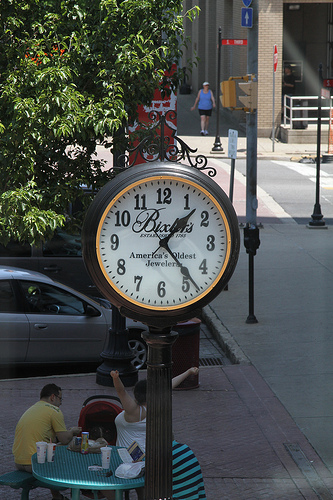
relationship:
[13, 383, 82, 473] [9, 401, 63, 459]
man wearing shirt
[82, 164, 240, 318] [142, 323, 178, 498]
clock on pole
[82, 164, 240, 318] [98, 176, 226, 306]
clock has face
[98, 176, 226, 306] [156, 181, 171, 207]
face has number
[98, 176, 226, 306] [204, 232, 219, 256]
face has number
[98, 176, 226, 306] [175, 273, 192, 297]
face has number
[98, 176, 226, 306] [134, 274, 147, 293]
face has number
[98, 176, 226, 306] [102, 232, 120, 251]
face has number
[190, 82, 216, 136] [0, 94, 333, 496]
person walking to floor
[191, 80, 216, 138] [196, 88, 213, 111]
person wearing blue top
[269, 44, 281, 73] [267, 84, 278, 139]
stop sign on pole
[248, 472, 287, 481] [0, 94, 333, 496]
crack in floor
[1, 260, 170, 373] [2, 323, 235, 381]
car parked in parking space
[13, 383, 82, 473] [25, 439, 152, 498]
man sitting at table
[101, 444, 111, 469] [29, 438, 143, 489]
beverage on top of table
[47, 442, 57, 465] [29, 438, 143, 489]
beverage on top of table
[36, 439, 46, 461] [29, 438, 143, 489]
beverage on top of table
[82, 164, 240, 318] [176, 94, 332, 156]
clock on sidewalk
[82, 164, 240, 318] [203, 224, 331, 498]
clock on sidewalk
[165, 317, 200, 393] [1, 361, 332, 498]
garbage can on sidewalk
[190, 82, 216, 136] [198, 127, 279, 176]
person walking on sidewalk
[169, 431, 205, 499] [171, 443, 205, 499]
person wearing shirt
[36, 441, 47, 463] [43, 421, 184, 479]
beverage on top of table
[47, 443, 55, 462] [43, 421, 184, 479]
beverage on top of table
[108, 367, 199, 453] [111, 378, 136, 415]
woman has lifted arm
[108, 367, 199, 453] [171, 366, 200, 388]
woman has right arm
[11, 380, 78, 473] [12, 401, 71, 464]
man wearing shirt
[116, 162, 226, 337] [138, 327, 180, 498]
clock on pole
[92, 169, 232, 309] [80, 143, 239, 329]
circle around face of clock